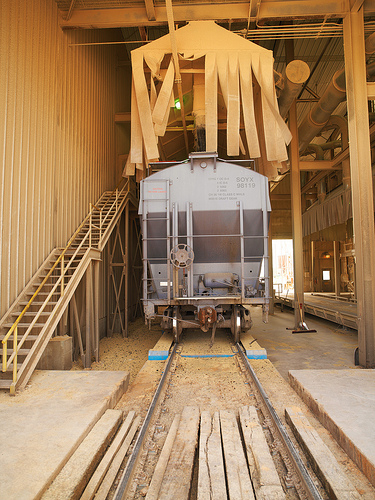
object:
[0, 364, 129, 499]
ground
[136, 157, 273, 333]
train car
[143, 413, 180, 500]
wood piece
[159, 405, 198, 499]
wood piece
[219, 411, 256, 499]
wood piece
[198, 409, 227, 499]
wood piece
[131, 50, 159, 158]
curtain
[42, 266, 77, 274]
stairs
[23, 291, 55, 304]
stairs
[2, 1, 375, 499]
building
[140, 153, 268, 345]
train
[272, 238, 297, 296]
door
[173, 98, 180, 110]
light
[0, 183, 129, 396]
staircase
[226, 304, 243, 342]
wheel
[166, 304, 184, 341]
wheel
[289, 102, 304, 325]
column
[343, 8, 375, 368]
support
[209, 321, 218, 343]
spray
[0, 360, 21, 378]
stairs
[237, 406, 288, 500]
planks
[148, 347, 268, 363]
paint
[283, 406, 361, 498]
planks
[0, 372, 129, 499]
platform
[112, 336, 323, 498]
track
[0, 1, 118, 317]
wall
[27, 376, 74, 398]
dust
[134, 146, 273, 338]
carrier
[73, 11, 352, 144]
ceiling